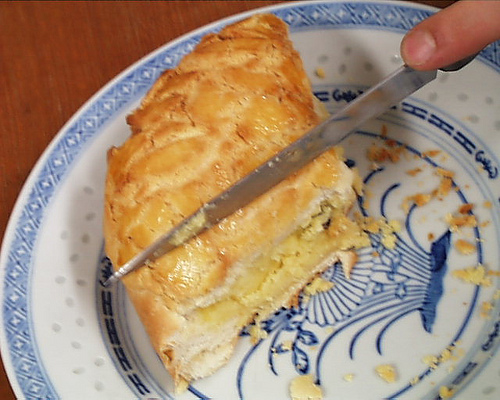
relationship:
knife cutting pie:
[331, 60, 402, 138] [122, 53, 368, 355]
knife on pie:
[331, 60, 402, 138] [122, 53, 368, 355]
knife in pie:
[331, 60, 402, 138] [122, 53, 368, 355]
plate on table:
[38, 101, 108, 245] [4, 14, 100, 96]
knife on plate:
[331, 60, 402, 138] [38, 101, 108, 245]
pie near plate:
[122, 53, 368, 355] [38, 101, 108, 245]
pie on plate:
[122, 53, 368, 355] [38, 101, 108, 245]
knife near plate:
[331, 60, 402, 138] [38, 101, 108, 245]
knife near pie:
[331, 60, 402, 138] [122, 53, 368, 355]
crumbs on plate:
[358, 138, 484, 269] [0, 1, 477, 397]